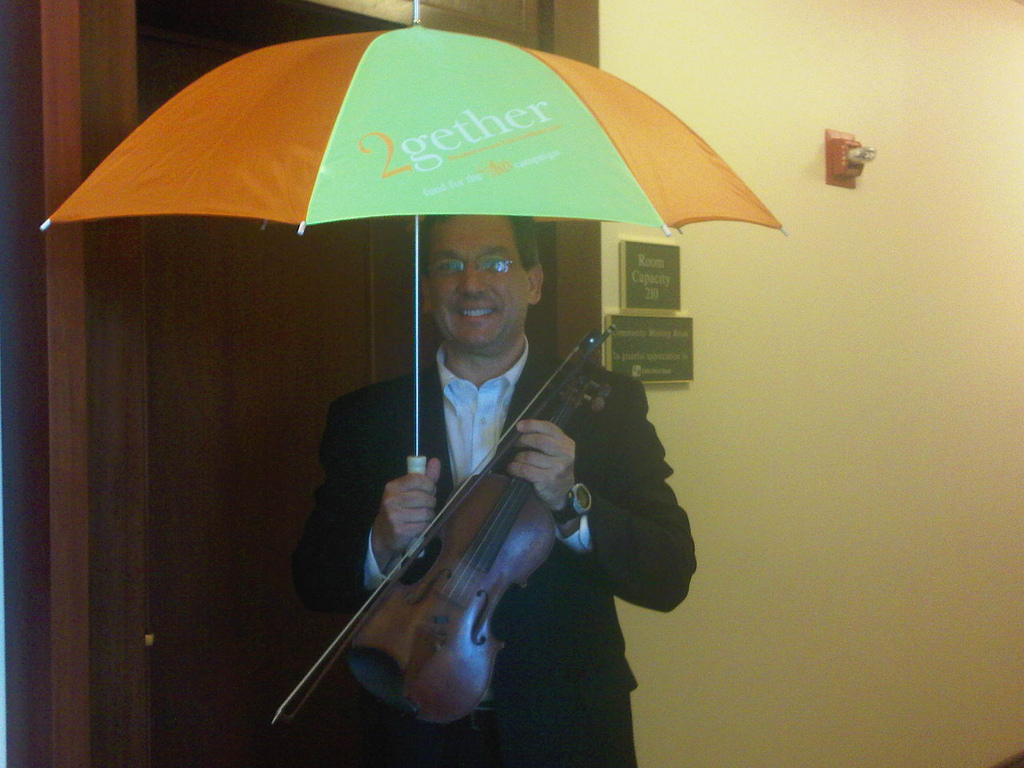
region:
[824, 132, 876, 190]
red fire alarm with a clear light bulb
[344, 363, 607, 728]
carved wooden violin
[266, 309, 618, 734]
tool used to play the violin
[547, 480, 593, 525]
watch with a black wrist band and a grey face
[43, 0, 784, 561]
orange and light green umbrella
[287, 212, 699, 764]
man wearing a suit while holding an umbrella and violin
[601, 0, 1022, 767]
beige painted wall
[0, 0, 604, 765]
dark brown, wooden door frame and door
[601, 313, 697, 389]
rectangular black and gold plaque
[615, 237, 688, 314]
rectangular black and gold plaque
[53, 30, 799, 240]
an orange and green umbrella in a man's hand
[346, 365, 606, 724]
a violin in a man's hand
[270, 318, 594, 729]
the bow of a violin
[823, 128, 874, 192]
fire alarm on a wall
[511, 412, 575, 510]
man's hand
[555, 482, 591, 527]
a watch on the arm of a man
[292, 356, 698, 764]
a black blazer on a man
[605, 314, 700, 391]
black and gold placard on the wall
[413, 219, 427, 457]
the pole of an umbrella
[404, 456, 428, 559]
a white umbrella handle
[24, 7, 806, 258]
a man holds umbrella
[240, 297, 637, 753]
a violin color brown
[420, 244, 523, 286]
glass on on a face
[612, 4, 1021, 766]
the wall is yellow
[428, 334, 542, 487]
the shirt is white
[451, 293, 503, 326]
the teeth are white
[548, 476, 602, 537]
a clock on the wrist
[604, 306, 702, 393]
sign on the wall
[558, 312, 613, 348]
end of the bow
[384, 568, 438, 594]
string on the violin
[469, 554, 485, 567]
string on the violin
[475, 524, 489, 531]
string on the violin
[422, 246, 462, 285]
eye of the man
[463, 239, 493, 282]
eye of the man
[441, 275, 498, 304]
nose of the man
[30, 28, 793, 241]
An orange and green umbrella.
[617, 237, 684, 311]
Black and square plate on the wall.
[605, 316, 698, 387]
A black and rectangular plate.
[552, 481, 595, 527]
A white watch with black straps.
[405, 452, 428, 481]
A white handle of the umbrella.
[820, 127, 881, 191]
An emergency light in red square.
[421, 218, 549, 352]
A face of an old man smiling.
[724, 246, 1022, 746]
Part of a plain cream wall.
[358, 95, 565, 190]
An orange and white writings.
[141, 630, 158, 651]
Part of a gold knob of the door.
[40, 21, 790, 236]
orange and green umbrella with orange and white letters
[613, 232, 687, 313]
black sign with gold lettering and frame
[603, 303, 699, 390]
black sign with gold lettering and frame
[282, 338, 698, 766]
black suit jacket with white shirt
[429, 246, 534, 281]
wire rimmed glasses with silver reflections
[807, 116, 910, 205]
fire alarm on the wall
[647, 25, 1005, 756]
wall is yellow in color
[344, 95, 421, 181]
umbrella has a number on it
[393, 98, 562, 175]
umbrella has text on it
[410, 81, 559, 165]
text is white in color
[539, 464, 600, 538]
man is wearing a watch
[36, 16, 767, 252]
umbrella is green and orange in color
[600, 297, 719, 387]
sign on the wall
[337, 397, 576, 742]
violin in brown in color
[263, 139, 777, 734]
a man wearing a suit